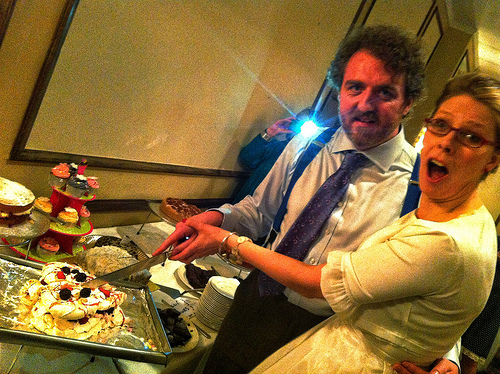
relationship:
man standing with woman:
[151, 22, 429, 372] [152, 25, 499, 373]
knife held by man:
[79, 250, 169, 289] [151, 22, 429, 372]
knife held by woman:
[79, 250, 169, 289] [152, 25, 499, 373]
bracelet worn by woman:
[218, 232, 255, 259] [152, 25, 499, 373]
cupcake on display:
[50, 158, 100, 235] [39, 161, 101, 258]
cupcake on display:
[34, 197, 51, 218] [39, 161, 101, 258]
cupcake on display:
[50, 164, 68, 189] [132, 190, 202, 264]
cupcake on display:
[50, 158, 100, 235] [132, 190, 202, 264]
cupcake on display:
[50, 158, 100, 235] [1, 174, 51, 264]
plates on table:
[193, 273, 240, 332] [0, 221, 251, 372]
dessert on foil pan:
[26, 259, 126, 340] [1, 247, 175, 359]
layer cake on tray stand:
[0, 167, 35, 220] [0, 207, 50, 257]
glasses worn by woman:
[416, 107, 495, 158] [152, 25, 499, 373]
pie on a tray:
[160, 195, 202, 222] [147, 200, 177, 227]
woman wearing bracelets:
[152, 25, 499, 373] [217, 232, 250, 265]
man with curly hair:
[151, 23, 429, 373] [360, 32, 432, 87]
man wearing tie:
[151, 23, 429, 373] [274, 141, 370, 256]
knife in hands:
[81, 250, 174, 289] [150, 207, 231, 263]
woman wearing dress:
[152, 25, 499, 373] [319, 205, 496, 372]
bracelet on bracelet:
[214, 228, 241, 258] [227, 233, 254, 264]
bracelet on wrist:
[214, 228, 241, 258] [215, 224, 252, 260]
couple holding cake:
[152, 23, 499, 372] [19, 258, 129, 341]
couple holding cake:
[152, 23, 499, 372] [0, 174, 36, 225]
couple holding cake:
[152, 23, 499, 372] [75, 245, 155, 286]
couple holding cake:
[152, 23, 499, 372] [159, 196, 202, 221]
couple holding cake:
[152, 23, 499, 372] [182, 259, 220, 292]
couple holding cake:
[152, 23, 499, 372] [153, 306, 192, 348]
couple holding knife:
[152, 23, 499, 372] [81, 249, 177, 286]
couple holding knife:
[152, 23, 499, 372] [159, 297, 211, 339]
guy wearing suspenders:
[160, 21, 425, 348] [245, 106, 342, 268]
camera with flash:
[287, 117, 340, 142] [301, 122, 318, 138]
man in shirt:
[151, 23, 429, 373] [313, 137, 405, 250]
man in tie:
[151, 23, 429, 373] [325, 152, 363, 219]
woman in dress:
[152, 25, 499, 373] [331, 190, 469, 354]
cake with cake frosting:
[28, 260, 173, 346] [25, 257, 139, 348]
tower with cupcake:
[4, 155, 103, 270] [44, 161, 70, 188]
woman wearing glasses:
[385, 63, 498, 305] [419, 113, 490, 150]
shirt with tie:
[208, 122, 418, 317] [256, 147, 366, 297]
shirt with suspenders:
[208, 122, 418, 317] [267, 120, 420, 239]